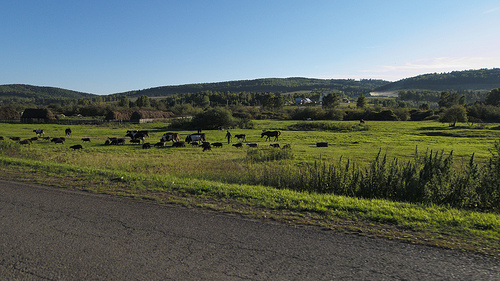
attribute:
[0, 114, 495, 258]
grass — pasture 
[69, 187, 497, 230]
grass — short, green, brown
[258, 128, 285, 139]
cow — brown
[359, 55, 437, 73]
clouds — white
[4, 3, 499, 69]
sky — blue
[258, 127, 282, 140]
horse — walking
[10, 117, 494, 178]
pasture — large, grassy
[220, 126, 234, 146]
person — walking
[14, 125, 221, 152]
livestock — grazing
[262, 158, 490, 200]
weeds — green, growing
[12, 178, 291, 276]
road — paved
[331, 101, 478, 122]
trees — green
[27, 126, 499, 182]
grass — green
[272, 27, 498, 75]
haze — white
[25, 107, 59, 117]
roof — straw